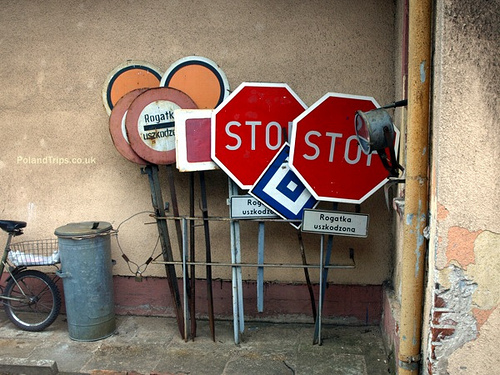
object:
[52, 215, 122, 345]
trash can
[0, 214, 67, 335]
bicycle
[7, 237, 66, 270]
basket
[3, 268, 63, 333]
wheel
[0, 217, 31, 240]
seat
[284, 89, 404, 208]
stop sign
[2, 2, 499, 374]
building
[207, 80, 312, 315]
stop sign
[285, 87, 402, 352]
stop sign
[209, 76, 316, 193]
stop sign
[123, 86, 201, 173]
sign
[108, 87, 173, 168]
sign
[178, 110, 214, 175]
sign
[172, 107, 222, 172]
sign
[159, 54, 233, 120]
sign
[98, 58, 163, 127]
sign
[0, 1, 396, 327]
side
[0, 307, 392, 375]
sidewalk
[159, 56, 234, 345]
sign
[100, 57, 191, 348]
sign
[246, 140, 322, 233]
sign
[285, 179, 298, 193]
central diamond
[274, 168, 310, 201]
second inner diamond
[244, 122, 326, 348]
sign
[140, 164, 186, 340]
post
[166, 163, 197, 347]
post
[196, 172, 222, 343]
post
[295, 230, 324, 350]
post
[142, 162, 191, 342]
post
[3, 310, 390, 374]
ground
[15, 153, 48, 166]
'poland'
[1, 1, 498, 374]
photo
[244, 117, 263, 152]
t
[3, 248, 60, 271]
cloth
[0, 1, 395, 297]
wall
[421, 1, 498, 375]
wall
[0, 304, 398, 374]
street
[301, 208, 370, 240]
sign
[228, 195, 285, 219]
sign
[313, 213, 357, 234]
polish designation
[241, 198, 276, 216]
polish designation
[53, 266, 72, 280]
handle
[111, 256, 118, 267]
handle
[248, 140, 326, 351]
road sign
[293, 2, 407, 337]
corner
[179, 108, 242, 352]
road sign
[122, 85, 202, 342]
road sign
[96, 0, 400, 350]
corner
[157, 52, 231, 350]
road sign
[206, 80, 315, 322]
road sign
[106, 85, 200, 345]
road sign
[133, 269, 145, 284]
lock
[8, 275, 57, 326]
spokes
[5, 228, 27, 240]
springs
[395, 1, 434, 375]
pipe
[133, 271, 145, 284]
padlock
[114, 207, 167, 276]
chain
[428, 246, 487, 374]
plaster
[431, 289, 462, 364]
bricks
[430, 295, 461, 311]
brick